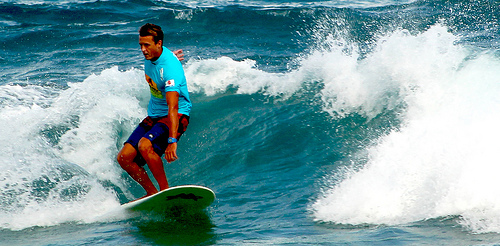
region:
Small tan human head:
[138, 21, 163, 58]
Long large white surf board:
[114, 183, 216, 218]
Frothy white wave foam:
[311, 24, 497, 231]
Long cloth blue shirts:
[121, 116, 191, 162]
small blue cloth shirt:
[140, 47, 193, 116]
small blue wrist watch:
[166, 137, 176, 144]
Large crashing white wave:
[1, 68, 138, 229]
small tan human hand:
[162, 143, 177, 160]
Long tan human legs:
[112, 137, 172, 203]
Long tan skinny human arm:
[166, 93, 178, 165]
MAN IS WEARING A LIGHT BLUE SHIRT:
[130, 46, 204, 127]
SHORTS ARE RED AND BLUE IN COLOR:
[123, 104, 205, 171]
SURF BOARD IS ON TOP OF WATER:
[118, 181, 220, 226]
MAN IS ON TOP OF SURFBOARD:
[110, 20, 226, 212]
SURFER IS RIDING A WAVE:
[44, 68, 287, 215]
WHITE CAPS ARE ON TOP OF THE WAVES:
[193, 44, 488, 148]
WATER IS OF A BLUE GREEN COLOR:
[188, 72, 373, 236]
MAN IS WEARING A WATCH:
[163, 131, 180, 148]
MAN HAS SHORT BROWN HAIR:
[140, 16, 160, 61]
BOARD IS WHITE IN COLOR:
[111, 184, 218, 221]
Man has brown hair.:
[138, 13, 181, 53]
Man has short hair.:
[128, 13, 179, 47]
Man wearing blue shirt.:
[121, 62, 226, 127]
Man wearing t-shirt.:
[131, 58, 202, 122]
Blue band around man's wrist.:
[160, 130, 185, 142]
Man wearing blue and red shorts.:
[119, 99, 205, 166]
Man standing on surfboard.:
[86, 130, 208, 232]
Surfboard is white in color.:
[106, 180, 208, 244]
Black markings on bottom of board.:
[168, 181, 208, 212]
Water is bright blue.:
[246, 130, 291, 205]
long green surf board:
[119, 185, 214, 220]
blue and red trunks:
[123, 113, 188, 151]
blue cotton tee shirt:
[138, 48, 193, 117]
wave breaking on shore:
[288, 52, 498, 231]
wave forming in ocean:
[2, 0, 499, 33]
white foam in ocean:
[3, 187, 124, 230]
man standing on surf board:
[113, 24, 217, 217]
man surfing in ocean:
[112, 22, 217, 219]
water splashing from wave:
[296, 5, 496, 50]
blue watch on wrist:
[167, 135, 177, 144]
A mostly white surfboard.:
[109, 185, 216, 215]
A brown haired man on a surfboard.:
[116, 22, 193, 195]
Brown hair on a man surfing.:
[138, 22, 163, 49]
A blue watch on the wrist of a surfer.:
[166, 135, 178, 142]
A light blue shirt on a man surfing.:
[142, 47, 192, 116]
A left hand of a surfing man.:
[164, 143, 176, 161]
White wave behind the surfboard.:
[1, 78, 146, 231]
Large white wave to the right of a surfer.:
[306, 23, 498, 237]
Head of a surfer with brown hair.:
[137, 23, 165, 60]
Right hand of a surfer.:
[170, 46, 186, 61]